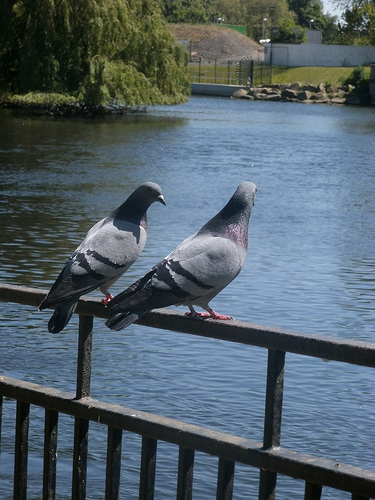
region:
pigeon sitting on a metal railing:
[106, 180, 260, 331]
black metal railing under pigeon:
[1, 282, 374, 498]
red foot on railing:
[201, 309, 233, 320]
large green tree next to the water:
[0, 0, 192, 108]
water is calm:
[0, 85, 372, 498]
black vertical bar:
[262, 345, 285, 448]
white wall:
[262, 40, 373, 67]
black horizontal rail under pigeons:
[1, 281, 373, 367]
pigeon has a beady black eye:
[145, 187, 151, 192]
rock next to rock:
[279, 88, 298, 98]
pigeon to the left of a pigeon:
[36, 181, 166, 331]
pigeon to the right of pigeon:
[94, 181, 257, 331]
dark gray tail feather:
[47, 300, 83, 328]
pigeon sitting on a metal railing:
[1, 283, 373, 499]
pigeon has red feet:
[209, 309, 233, 321]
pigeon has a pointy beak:
[157, 194, 166, 205]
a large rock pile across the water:
[230, 78, 355, 103]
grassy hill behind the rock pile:
[274, 63, 370, 86]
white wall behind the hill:
[264, 42, 374, 68]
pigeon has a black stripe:
[86, 250, 126, 270]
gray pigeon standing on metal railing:
[97, 177, 262, 331]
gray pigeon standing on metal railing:
[34, 176, 169, 335]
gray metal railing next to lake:
[0, 275, 374, 498]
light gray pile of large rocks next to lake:
[229, 79, 371, 104]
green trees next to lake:
[0, 0, 193, 116]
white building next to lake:
[261, 24, 374, 68]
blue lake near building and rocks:
[0, 90, 374, 499]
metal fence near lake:
[112, 51, 274, 89]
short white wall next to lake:
[140, 79, 255, 98]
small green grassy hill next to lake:
[164, 61, 373, 94]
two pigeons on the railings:
[56, 152, 263, 336]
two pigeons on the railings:
[26, 156, 259, 341]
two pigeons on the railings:
[44, 162, 284, 343]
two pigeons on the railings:
[38, 163, 257, 355]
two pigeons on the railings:
[54, 150, 273, 375]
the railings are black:
[47, 372, 296, 497]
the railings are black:
[23, 346, 305, 498]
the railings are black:
[25, 333, 281, 498]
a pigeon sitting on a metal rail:
[34, 167, 167, 338]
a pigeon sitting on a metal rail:
[100, 181, 258, 333]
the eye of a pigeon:
[143, 186, 153, 196]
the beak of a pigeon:
[157, 192, 169, 206]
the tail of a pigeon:
[101, 284, 147, 333]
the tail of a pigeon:
[34, 281, 86, 336]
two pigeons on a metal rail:
[35, 180, 277, 330]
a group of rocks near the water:
[224, 75, 374, 105]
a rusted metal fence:
[0, 280, 372, 496]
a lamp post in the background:
[307, 17, 314, 29]